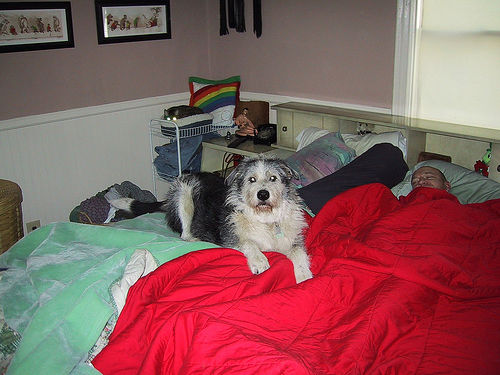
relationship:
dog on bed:
[165, 147, 318, 295] [72, 243, 259, 348]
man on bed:
[400, 165, 451, 206] [72, 243, 259, 348]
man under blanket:
[400, 165, 451, 206] [313, 194, 474, 374]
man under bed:
[400, 165, 451, 206] [72, 243, 259, 348]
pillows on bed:
[269, 110, 409, 238] [72, 243, 259, 348]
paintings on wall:
[1, 3, 186, 59] [10, 68, 121, 107]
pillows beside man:
[269, 110, 409, 238] [400, 165, 451, 206]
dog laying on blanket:
[165, 147, 318, 295] [90, 182, 497, 373]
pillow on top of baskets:
[188, 75, 241, 128] [147, 118, 237, 190]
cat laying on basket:
[160, 103, 209, 127] [146, 119, 236, 137]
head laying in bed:
[408, 166, 451, 194] [8, 97, 498, 369]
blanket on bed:
[0, 213, 222, 373] [8, 97, 498, 369]